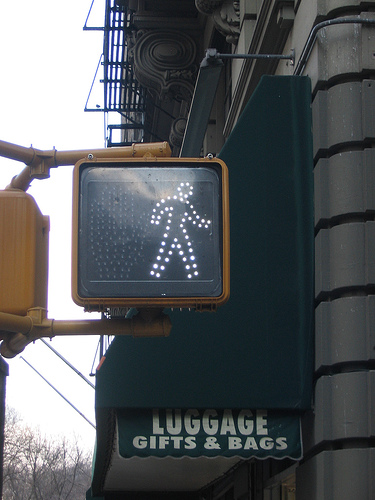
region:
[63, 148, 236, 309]
street sign on the pole.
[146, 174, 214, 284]
Man walking character on sign.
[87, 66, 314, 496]
Awning on the building.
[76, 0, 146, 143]
Black metal fire escape.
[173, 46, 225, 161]
Light on the building.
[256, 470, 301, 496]
Window in the building.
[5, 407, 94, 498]
Trees in the background.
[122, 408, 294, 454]
White letters on the awning.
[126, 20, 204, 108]
Cement scroll work on the building.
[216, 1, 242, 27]
Cement leaf on the building.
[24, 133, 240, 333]
The sign shows to walk.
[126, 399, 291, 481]
The sign is advertising gifts.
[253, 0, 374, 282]
The building is sandstone.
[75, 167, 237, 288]
The sign has white bulbs.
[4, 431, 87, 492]
There are no leaves on the trees.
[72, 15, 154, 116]
There is a fire escape.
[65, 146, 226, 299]
Walking is permitted.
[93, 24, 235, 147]
The building has carved sandstone.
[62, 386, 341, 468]
The sign is green.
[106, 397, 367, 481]
The letters are white.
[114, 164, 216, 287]
walk symbol on signal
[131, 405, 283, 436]
sign that says "luggage"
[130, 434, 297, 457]
sign that says "gifts & bags"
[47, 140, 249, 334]
traffic signal for pedestrians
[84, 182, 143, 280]
unlit signal for no walking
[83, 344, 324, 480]
green awning for shop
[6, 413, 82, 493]
trees with no leaves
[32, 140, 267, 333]
signal for foot traffic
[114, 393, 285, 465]
sign with white letters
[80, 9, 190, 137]
fire escape above shop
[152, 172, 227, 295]
figure of person walking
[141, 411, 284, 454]
sign under awning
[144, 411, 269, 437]
word luggage in big white letters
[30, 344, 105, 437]
telephone wires to the right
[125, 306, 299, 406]
awning is green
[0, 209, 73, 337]
yellow box to hold signal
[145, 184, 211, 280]
figure in white means walk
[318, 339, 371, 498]
edge of building is gray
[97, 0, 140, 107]
fire escape on top of building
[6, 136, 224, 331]
a yellow sign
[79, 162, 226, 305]
a cross walk sign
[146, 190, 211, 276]
a white person on a sign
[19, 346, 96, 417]
wires in the sky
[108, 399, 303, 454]
writing on the sign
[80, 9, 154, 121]
a ledge above the sign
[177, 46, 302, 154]
a light hanging from the building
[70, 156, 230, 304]
yellow and black walk or don't walk sign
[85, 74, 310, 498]
a dark green business awning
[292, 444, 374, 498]
a wall cladding or siding of a building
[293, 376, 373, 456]
a wall cladding or siding of a building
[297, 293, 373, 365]
a wall cladding or siding of a building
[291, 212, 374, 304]
a wall cladding or siding of a building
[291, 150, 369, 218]
a wall cladding or siding of a building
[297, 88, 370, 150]
a wall cladding or siding of a building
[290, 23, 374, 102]
a wall cladding or siding of a building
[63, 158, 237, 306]
pedestrian crossing signage on a post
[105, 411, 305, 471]
luggage gifts & bags signage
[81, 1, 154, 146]
steel fire exit outdoor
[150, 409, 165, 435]
white letter on the green sign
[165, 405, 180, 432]
white letter on the green sign